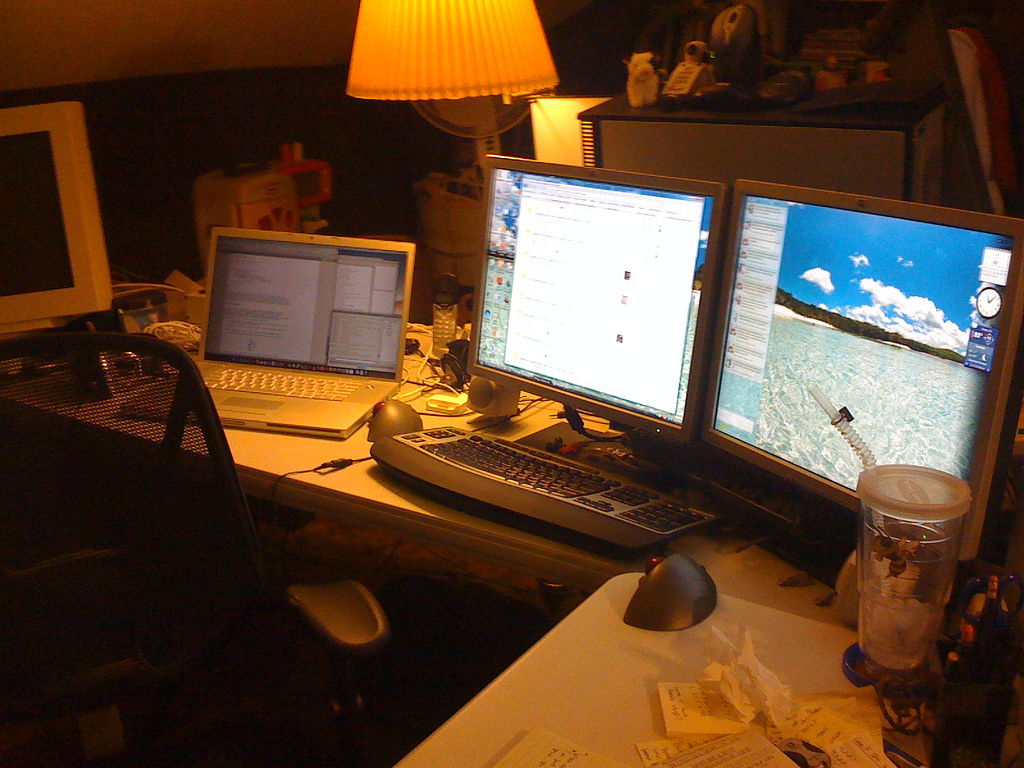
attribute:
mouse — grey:
[624, 554, 713, 624]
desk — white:
[43, 340, 1014, 757]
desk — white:
[2, 294, 860, 625]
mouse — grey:
[371, 396, 423, 440]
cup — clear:
[806, 387, 975, 679]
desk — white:
[350, 566, 1022, 759]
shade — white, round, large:
[348, 0, 558, 104]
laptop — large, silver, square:
[119, 225, 416, 422]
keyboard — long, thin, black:
[369, 424, 724, 559]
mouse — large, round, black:
[620, 549, 716, 627]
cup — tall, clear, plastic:
[853, 461, 972, 678]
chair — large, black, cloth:
[0, 329, 387, 749]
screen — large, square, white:
[0, 96, 117, 336]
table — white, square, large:
[373, 564, 942, 761]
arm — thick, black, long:
[296, 573, 394, 656]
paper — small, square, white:
[656, 677, 745, 732]